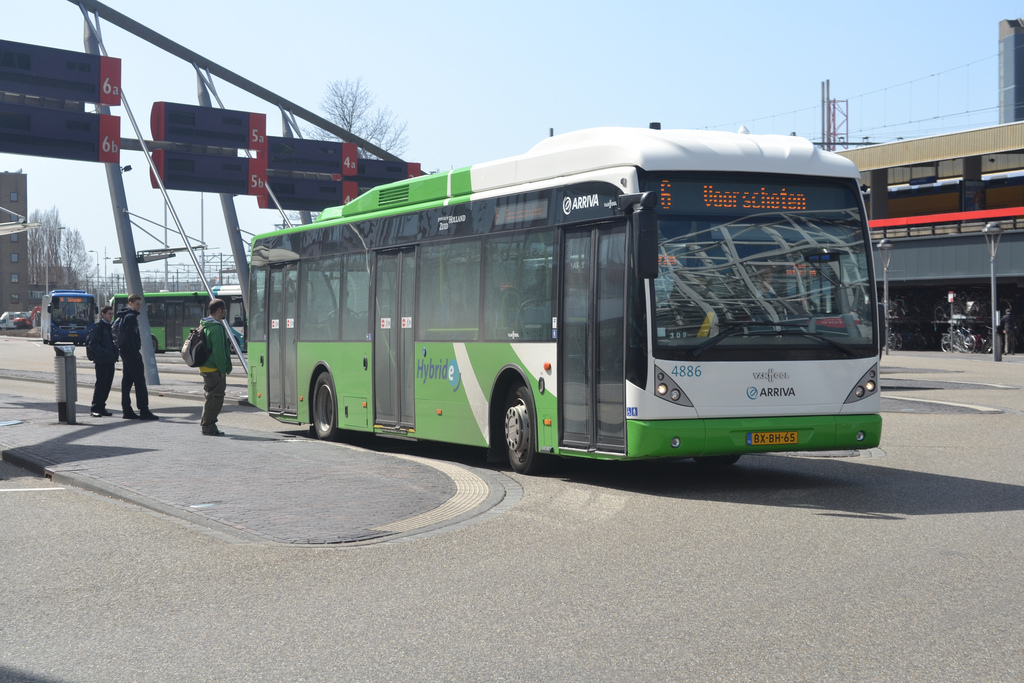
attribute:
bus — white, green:
[216, 116, 880, 474]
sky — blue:
[716, 36, 768, 75]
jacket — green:
[177, 289, 242, 430]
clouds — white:
[365, 21, 608, 132]